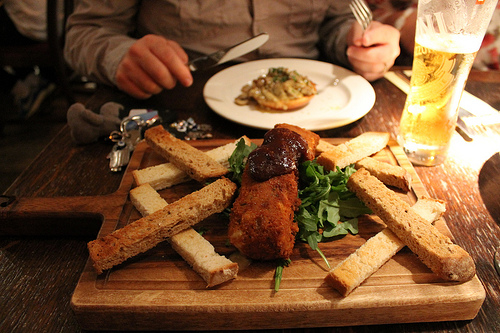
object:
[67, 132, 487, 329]
board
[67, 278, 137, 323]
edge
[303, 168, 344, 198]
leaf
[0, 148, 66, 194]
line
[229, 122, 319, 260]
cake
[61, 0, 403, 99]
person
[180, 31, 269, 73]
knife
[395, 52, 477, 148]
beer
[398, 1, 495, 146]
glass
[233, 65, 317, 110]
food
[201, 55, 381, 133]
plate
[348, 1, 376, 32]
fork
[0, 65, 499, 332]
table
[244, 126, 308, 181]
sauce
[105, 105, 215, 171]
keys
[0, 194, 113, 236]
handle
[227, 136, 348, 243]
lettuce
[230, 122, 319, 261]
meat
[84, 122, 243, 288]
breadsticks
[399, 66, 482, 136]
napkin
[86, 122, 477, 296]
meal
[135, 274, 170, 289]
part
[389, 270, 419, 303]
part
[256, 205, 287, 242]
part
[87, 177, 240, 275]
sticks